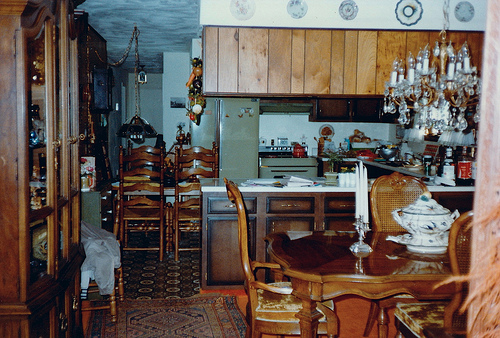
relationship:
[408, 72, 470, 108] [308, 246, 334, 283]
chandelier above table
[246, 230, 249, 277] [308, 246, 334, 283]
chair near table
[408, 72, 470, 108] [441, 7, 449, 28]
chandelier in chain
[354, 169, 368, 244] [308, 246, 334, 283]
candles on table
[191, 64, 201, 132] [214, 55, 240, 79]
fruit on wall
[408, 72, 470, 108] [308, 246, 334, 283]
chandelier over table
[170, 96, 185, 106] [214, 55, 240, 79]
picture on wall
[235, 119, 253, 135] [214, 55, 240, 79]
refigerator near wall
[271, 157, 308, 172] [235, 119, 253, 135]
stove near refigerator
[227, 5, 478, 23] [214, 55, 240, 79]
dishes on wall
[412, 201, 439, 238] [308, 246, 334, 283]
tureen on table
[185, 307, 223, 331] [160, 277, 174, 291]
rug on floor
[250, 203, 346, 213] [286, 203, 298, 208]
drawers have handles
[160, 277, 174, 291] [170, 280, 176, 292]
floor has pattern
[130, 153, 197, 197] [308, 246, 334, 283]
chairs near table